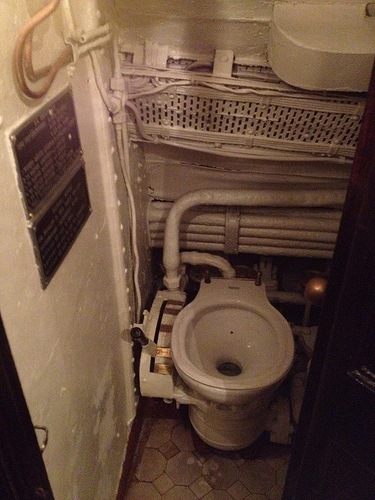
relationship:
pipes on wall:
[149, 186, 348, 281] [100, 1, 373, 408]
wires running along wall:
[104, 109, 162, 229] [105, 4, 371, 153]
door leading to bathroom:
[274, 56, 370, 498] [2, 0, 373, 498]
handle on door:
[28, 420, 57, 453] [274, 56, 370, 498]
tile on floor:
[132, 452, 282, 494] [216, 470, 267, 495]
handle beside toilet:
[129, 325, 157, 355] [172, 274, 293, 436]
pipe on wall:
[7, 9, 85, 91] [7, 4, 126, 120]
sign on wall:
[5, 83, 118, 291] [1, 2, 139, 341]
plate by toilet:
[152, 346, 175, 359] [168, 256, 301, 453]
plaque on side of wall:
[9, 83, 94, 291] [0, 0, 137, 497]